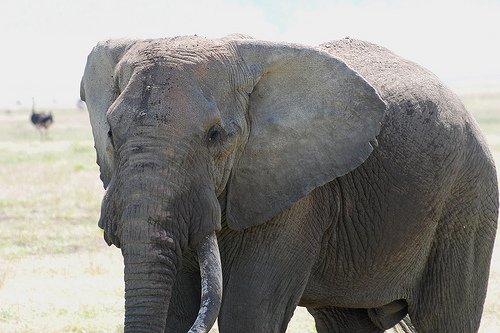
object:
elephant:
[80, 35, 500, 331]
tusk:
[184, 229, 223, 331]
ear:
[225, 41, 387, 231]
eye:
[210, 128, 221, 142]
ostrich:
[30, 95, 54, 141]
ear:
[79, 38, 133, 189]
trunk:
[113, 149, 193, 332]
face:
[98, 60, 244, 332]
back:
[307, 35, 469, 126]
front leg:
[219, 230, 317, 331]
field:
[2, 105, 126, 332]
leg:
[406, 289, 487, 331]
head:
[80, 35, 390, 330]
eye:
[106, 123, 114, 143]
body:
[170, 38, 499, 330]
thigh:
[309, 307, 377, 331]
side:
[144, 38, 500, 331]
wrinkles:
[343, 225, 357, 272]